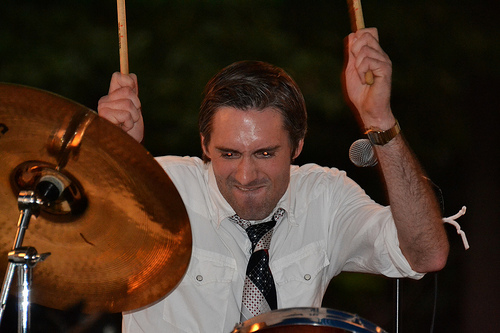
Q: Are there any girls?
A: No, there are no girls.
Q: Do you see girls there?
A: No, there are no girls.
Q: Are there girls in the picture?
A: No, there are no girls.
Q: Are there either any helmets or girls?
A: No, there are no girls or helmets.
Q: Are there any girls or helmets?
A: No, there are no girls or helmets.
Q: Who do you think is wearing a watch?
A: The man is wearing a watch.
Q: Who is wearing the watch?
A: The man is wearing a watch.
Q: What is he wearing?
A: The man is wearing a watch.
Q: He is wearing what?
A: The man is wearing a watch.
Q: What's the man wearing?
A: The man is wearing a watch.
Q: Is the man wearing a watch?
A: Yes, the man is wearing a watch.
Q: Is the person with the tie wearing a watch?
A: Yes, the man is wearing a watch.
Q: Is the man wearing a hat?
A: No, the man is wearing a watch.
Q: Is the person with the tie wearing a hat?
A: No, the man is wearing a watch.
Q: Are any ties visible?
A: Yes, there is a tie.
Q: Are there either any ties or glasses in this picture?
A: Yes, there is a tie.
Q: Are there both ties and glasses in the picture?
A: No, there is a tie but no glasses.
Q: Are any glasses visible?
A: No, there are no glasses.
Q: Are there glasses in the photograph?
A: No, there are no glasses.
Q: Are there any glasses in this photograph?
A: No, there are no glasses.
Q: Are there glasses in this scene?
A: No, there are no glasses.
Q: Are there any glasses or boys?
A: No, there are no glasses or boys.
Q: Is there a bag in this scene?
A: No, there are no bags.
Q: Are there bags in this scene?
A: No, there are no bags.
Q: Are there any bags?
A: No, there are no bags.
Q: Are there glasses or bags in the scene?
A: No, there are no bags or glasses.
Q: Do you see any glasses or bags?
A: No, there are no bags or glasses.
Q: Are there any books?
A: No, there are no books.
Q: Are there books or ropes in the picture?
A: No, there are no books or ropes.